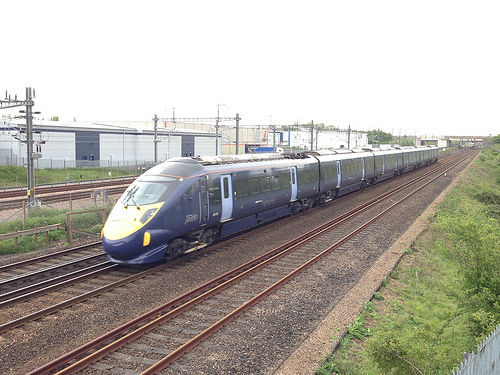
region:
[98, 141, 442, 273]
Passenger train on the track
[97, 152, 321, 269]
Front car of the passenger train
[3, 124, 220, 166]
Building next to the train tracks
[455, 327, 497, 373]
White picket fence in the corner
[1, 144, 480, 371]
Gravel along both sides of the train tracks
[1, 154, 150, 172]
Steel fence in front of the building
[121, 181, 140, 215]
Windshield wipers on the train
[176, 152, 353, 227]
the train has windows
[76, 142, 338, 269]
the train has windows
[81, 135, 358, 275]
the train has windows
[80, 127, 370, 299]
the train has windows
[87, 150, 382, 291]
the train has windows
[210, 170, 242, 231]
train's door is white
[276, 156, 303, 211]
train's door is white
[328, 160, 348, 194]
train's door is white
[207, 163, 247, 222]
train's door is white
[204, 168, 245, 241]
train's door is white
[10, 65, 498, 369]
a scene during the day time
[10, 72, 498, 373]
a scene outside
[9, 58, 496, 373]
an image of a train track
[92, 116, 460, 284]
a blue train riding down the track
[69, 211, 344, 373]
a brown tracks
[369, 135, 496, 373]
a green bushes on the right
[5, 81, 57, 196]
a brown wood pole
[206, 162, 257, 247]
a white train door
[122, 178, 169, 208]
window on a train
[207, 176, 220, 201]
window on a train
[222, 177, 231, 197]
window on a train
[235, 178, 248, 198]
window on a train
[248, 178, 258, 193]
window on a train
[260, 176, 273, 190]
window on a train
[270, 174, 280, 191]
window on a train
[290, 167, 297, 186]
window on a train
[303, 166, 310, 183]
window on a train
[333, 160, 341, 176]
window on a train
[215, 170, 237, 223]
light blue door on a train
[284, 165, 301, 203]
light blue door on a train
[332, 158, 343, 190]
light blue door on a train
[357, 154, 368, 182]
light blue door on a train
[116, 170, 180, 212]
slanted wind shield on the front of a train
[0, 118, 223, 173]
long white building with blue doors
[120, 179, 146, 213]
two wind shield wipers on a train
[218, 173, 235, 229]
blue door with window in it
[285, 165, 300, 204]
blue door with window in it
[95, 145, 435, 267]
Long train on tracks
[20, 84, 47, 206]
Metal pole near tracks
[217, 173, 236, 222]
White door on a train